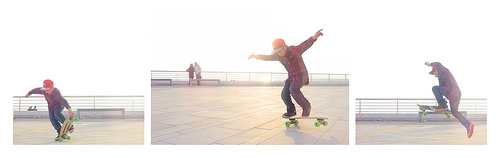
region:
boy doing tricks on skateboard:
[12, 59, 92, 149]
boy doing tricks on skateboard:
[272, 27, 332, 146]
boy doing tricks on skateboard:
[422, 41, 469, 150]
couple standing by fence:
[184, 51, 204, 80]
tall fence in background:
[22, 91, 159, 118]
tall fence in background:
[159, 66, 331, 95]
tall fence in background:
[361, 96, 475, 126]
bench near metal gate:
[81, 105, 128, 114]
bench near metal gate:
[192, 76, 217, 87]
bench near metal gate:
[147, 77, 167, 92]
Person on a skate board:
[410, 48, 487, 138]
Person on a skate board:
[261, 32, 333, 143]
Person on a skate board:
[28, 71, 83, 140]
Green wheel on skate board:
[279, 115, 291, 131]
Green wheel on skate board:
[290, 118, 302, 130]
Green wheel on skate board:
[310, 116, 322, 137]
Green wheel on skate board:
[321, 116, 328, 133]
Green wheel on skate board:
[410, 103, 438, 130]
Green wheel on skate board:
[443, 111, 451, 122]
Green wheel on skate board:
[55, 106, 84, 141]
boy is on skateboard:
[266, 42, 326, 132]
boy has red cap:
[266, 25, 295, 50]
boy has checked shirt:
[266, 50, 310, 92]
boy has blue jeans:
[278, 80, 310, 99]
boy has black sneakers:
[277, 99, 318, 124]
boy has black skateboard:
[283, 107, 320, 130]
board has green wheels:
[285, 116, 342, 130]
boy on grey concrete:
[171, 86, 265, 135]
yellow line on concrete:
[356, 115, 407, 150]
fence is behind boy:
[359, 100, 418, 113]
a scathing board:
[319, 116, 327, 123]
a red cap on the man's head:
[43, 79, 53, 87]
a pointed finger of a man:
[317, 28, 324, 32]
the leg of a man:
[299, 100, 310, 112]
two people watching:
[188, 62, 203, 74]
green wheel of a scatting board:
[67, 119, 72, 124]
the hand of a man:
[246, 54, 268, 61]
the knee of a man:
[287, 85, 299, 94]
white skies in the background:
[89, 8, 162, 59]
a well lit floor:
[191, 111, 238, 138]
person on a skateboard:
[20, 76, 82, 143]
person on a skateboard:
[238, 24, 342, 132]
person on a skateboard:
[410, 52, 480, 141]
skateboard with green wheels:
[55, 109, 81, 147]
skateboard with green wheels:
[282, 111, 332, 130]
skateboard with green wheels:
[410, 102, 457, 119]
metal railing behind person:
[12, 90, 146, 121]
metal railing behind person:
[152, 64, 351, 84]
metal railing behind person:
[355, 96, 492, 112]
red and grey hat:
[270, 36, 285, 56]